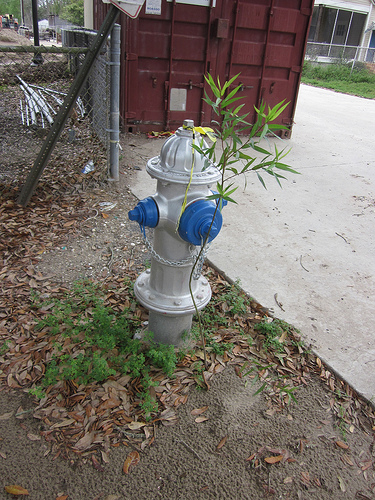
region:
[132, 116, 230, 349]
the silver and blue hydrant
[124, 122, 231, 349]
the silver and blue fire hydrant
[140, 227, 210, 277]
the chains on the fire hydrant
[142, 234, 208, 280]
the chains on the hydrant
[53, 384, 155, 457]
the brown leaves on the ground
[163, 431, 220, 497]
the dirt on the ground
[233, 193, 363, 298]
the cement next to the hydrant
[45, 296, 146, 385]
the greenery next to the hydrant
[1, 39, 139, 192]
the chain link fence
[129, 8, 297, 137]
the maroon dumpster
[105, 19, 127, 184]
the pole is gray in color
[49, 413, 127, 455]
the leaves are dead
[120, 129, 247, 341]
the hydrant is silver and blue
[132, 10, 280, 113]
the storage container is maroon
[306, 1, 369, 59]
this house has a screened porch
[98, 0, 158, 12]
the sign is white and red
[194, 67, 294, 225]
the weed has green leaves on it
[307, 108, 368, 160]
the driveway is gray in color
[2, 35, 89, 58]
this pipe has moss on it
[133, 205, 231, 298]
the chain is hooked to the hydrant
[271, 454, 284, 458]
brown leaves laying on the ground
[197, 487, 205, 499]
brown dirt is on the ground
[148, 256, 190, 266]
change hanging off the fire hydrant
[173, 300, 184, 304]
silver bolts around the bottom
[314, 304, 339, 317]
ground is made out of concrete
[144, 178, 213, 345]
fire hydrant in the ground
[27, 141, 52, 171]
pole is leaning in the ground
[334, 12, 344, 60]
glass window in the building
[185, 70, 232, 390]
tall weeds growing along the side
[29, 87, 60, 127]
iron poles laying behind the fence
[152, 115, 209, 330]
silver fire hydrant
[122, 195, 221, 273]
blue plugs chained onto hydrant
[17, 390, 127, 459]
small dried leaves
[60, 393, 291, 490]
raindrops left ground riddled with dents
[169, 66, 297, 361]
tree grows wild next to hydrant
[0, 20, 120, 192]
chain link fence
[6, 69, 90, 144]
pipes lay on the ground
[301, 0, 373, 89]
a sunroom beyond the fence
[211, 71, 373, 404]
a concrete drive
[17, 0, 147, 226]
a tipped street sign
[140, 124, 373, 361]
a sidewalk next to the hydrant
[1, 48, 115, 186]
a metal fence in the yard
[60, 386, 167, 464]
a pile of leaves on the ground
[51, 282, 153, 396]
a green plant on the ground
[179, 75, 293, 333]
a tall plant next to the hydrant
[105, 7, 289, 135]
a big metal storage container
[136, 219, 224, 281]
chains on the fire hydrant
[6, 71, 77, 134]
metal poles on the ground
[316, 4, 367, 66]
a house in the background